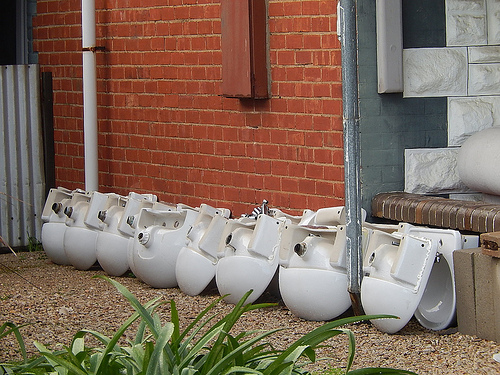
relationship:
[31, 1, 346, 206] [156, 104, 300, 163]
wall made of bricks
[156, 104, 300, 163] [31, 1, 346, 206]
bricks in wall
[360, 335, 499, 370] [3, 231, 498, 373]
gravel covering ground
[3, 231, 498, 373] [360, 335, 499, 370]
ground under gravel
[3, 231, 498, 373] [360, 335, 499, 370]
ground covered with gravel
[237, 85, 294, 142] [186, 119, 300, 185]
wall with brick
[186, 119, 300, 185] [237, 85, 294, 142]
brick in wall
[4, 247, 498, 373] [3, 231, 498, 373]
gravel on ground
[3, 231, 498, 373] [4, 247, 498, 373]
ground with gravel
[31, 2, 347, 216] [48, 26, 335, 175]
brick wall making up building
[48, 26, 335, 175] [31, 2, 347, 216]
building with brick wall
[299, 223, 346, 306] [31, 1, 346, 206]
sink leaning against wall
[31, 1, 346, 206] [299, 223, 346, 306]
wall with sink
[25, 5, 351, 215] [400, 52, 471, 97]
wall with block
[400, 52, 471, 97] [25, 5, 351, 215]
block in wall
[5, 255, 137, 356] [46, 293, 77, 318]
dirt with stone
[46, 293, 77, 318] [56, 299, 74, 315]
stone near wall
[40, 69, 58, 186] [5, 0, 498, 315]
shadow on building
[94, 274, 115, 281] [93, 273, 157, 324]
tip of a leaf